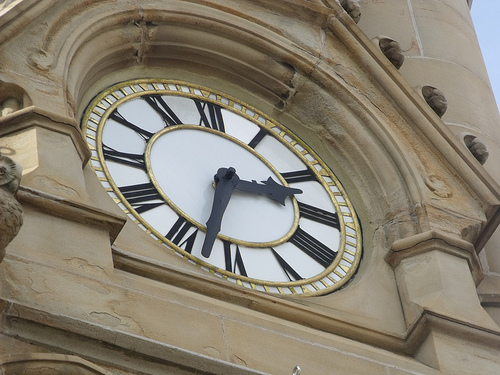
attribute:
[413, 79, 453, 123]
knob — gray cement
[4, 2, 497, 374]
building — gray cement, stone, big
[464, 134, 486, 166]
knob — gray cement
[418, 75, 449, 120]
knob — gray cement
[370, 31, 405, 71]
knob — gray cement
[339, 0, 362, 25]
knob — gray cement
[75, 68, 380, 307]
filagree — gold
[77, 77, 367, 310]
clock — black, white, big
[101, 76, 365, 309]
face — white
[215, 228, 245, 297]
number — four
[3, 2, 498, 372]
wall — clean, smooth, brown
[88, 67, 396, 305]
clock — white, crisp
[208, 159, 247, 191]
pin — black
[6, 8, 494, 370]
building surface — stone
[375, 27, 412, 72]
stone — dark brown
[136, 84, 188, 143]
number — black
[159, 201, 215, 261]
number — black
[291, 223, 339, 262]
roman numerals — black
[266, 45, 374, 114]
sculptures — round